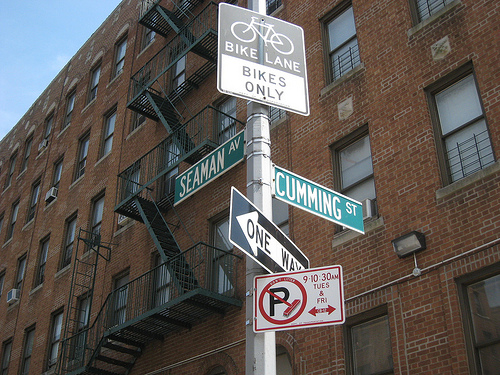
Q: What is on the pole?
A: The sign is on the pole.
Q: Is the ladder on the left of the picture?
A: Yes, the ladder is on the left of the image.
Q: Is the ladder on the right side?
A: No, the ladder is on the left of the image.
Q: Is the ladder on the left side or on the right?
A: The ladder is on the left of the image.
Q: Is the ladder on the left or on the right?
A: The ladder is on the left of the image.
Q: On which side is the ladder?
A: The ladder is on the left of the image.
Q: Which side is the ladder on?
A: The ladder is on the left of the image.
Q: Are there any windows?
A: Yes, there are windows.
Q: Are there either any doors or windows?
A: Yes, there are windows.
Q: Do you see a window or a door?
A: Yes, there are windows.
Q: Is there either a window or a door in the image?
A: Yes, there are windows.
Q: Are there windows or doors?
A: Yes, there are windows.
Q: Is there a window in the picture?
A: Yes, there is a window.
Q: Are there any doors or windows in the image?
A: Yes, there is a window.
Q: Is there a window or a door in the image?
A: Yes, there is a window.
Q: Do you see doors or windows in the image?
A: Yes, there is a window.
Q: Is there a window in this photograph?
A: Yes, there is a window.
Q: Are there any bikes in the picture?
A: Yes, there is a bike.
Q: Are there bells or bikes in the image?
A: Yes, there is a bike.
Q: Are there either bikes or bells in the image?
A: Yes, there is a bike.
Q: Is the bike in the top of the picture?
A: Yes, the bike is in the top of the image.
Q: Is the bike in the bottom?
A: No, the bike is in the top of the image.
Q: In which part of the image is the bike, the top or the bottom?
A: The bike is in the top of the image.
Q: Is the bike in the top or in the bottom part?
A: The bike is in the top of the image.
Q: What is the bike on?
A: The bike is on the sign.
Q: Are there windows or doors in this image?
A: Yes, there is a window.